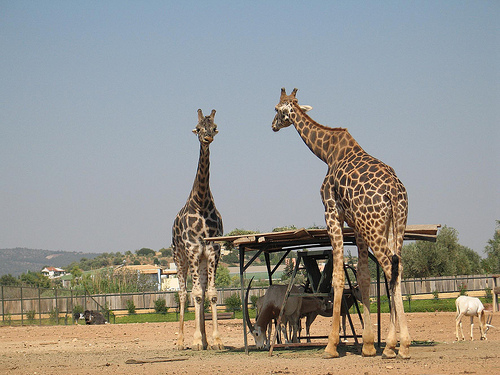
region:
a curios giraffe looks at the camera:
[166, 105, 232, 353]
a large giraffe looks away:
[265, 82, 435, 369]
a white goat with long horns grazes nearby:
[453, 283, 498, 349]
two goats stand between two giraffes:
[239, 271, 329, 347]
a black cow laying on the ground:
[76, 301, 114, 327]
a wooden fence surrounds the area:
[3, 286, 167, 308]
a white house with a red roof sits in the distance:
[43, 265, 65, 280]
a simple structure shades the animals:
[214, 234, 371, 332]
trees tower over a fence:
[411, 224, 482, 271]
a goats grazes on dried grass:
[239, 283, 283, 355]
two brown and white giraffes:
[166, 78, 413, 357]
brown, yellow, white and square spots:
[265, 81, 412, 366]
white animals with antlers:
[238, 262, 498, 354]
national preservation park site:
[2, 215, 499, 374]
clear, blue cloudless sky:
[3, 0, 498, 271]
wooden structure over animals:
[202, 214, 449, 348]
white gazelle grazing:
[449, 295, 496, 344]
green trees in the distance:
[5, 217, 499, 297]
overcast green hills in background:
[3, 242, 187, 279]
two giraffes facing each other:
[161, 77, 416, 364]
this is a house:
[39, 265, 63, 280]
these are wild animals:
[170, 88, 410, 359]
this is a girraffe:
[171, 108, 224, 351]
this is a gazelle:
[454, 293, 494, 341]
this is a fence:
[1, 289, 173, 314]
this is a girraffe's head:
[191, 108, 220, 145]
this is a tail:
[386, 193, 400, 295]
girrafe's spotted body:
[335, 155, 375, 211]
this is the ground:
[1, 327, 176, 369]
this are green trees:
[421, 243, 486, 274]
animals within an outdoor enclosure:
[45, 51, 468, 362]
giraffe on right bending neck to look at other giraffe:
[160, 65, 420, 360]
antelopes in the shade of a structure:
[151, 200, 408, 352]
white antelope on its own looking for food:
[440, 276, 495, 346]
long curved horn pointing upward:
[231, 251, 276, 331]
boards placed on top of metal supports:
[190, 216, 436, 356]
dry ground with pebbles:
[60, 326, 465, 361]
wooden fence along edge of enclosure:
[15, 275, 495, 326]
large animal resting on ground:
[61, 291, 113, 331]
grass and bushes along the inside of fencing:
[11, 280, 474, 325]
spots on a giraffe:
[338, 169, 376, 197]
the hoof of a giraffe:
[320, 344, 348, 359]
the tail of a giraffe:
[380, 194, 416, 284]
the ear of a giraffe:
[275, 104, 288, 111]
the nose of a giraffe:
[201, 134, 211, 139]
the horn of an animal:
[239, 279, 264, 324]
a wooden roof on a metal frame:
[227, 227, 334, 268]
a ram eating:
[443, 282, 492, 349]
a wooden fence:
[50, 293, 129, 308]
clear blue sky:
[83, 84, 150, 140]